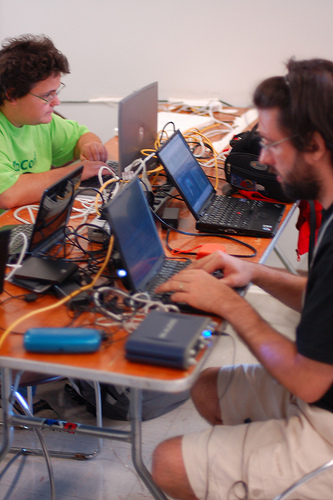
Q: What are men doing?
A: Using computers.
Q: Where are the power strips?
A: On the table.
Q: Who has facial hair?
A: The man on the right.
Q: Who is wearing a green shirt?
A: The man on the left.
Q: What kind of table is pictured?
A: A folding table.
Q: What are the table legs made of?
A: Metal.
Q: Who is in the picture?
A: Men and women.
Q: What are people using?
A: Computers.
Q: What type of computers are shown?
A: Laptops.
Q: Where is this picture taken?
A: A classroom.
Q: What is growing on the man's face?
A: A beard.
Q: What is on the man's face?
A: Glasses.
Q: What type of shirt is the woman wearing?
A: Green.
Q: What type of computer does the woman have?
A: An apple.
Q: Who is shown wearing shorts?
A: The man on the right.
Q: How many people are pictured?
A: Two.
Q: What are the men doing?
A: Using their computers.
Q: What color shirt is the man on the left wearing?
A: Green.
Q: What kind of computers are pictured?
A: Laptops.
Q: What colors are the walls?
A: White.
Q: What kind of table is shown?
A: A folding table.